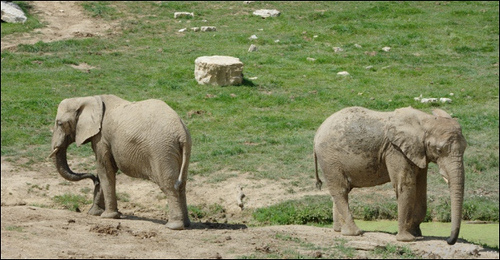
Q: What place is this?
A: It is a field.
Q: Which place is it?
A: It is a field.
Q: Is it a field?
A: Yes, it is a field.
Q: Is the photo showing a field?
A: Yes, it is showing a field.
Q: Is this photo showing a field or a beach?
A: It is showing a field.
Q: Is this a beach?
A: No, it is a field.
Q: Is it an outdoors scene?
A: Yes, it is outdoors.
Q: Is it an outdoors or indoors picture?
A: It is outdoors.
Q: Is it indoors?
A: No, it is outdoors.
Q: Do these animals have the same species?
A: Yes, all the animals are elephants.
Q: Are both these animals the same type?
A: Yes, all the animals are elephants.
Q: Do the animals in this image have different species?
A: No, all the animals are elephants.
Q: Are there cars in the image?
A: No, there are no cars.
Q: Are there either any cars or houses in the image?
A: No, there are no cars or houses.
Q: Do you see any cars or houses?
A: No, there are no cars or houses.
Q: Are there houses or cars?
A: No, there are no cars or houses.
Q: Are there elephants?
A: Yes, there is an elephant.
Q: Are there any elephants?
A: Yes, there is an elephant.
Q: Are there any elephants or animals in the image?
A: Yes, there is an elephant.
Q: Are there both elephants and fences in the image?
A: No, there is an elephant but no fences.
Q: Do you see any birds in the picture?
A: No, there are no birds.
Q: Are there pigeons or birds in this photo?
A: No, there are no birds or pigeons.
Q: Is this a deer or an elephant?
A: This is an elephant.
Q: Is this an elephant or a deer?
A: This is an elephant.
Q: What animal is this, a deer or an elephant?
A: This is an elephant.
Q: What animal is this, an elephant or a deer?
A: This is an elephant.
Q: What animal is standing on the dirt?
A: The elephant is standing on the dirt.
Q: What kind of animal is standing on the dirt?
A: The animal is an elephant.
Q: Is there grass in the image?
A: Yes, there is grass.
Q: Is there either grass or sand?
A: Yes, there is grass.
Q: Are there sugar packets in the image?
A: No, there are no sugar packets.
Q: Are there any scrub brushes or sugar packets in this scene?
A: No, there are no sugar packets or scrub brushes.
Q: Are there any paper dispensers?
A: No, there are no paper dispensers.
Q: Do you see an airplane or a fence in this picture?
A: No, there are no fences or airplanes.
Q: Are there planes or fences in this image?
A: No, there are no fences or planes.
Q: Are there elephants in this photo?
A: Yes, there is an elephant.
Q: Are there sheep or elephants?
A: Yes, there is an elephant.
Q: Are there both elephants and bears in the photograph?
A: No, there is an elephant but no bears.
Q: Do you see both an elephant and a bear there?
A: No, there is an elephant but no bears.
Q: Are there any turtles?
A: No, there are no turtles.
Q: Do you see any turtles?
A: No, there are no turtles.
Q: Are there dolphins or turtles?
A: No, there are no turtles or dolphins.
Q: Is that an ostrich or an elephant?
A: That is an elephant.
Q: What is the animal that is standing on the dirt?
A: The animal is an elephant.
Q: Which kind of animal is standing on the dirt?
A: The animal is an elephant.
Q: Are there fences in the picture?
A: No, there are no fences.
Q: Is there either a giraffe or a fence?
A: No, there are no fences or giraffes.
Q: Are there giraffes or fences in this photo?
A: No, there are no fences or giraffes.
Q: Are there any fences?
A: No, there are no fences.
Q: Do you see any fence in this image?
A: No, there are no fences.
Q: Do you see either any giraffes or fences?
A: No, there are no fences or giraffes.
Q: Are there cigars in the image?
A: No, there are no cigars.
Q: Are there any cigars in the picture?
A: No, there are no cigars.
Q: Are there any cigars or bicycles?
A: No, there are no cigars or bicycles.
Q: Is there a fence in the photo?
A: No, there are no fences.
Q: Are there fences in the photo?
A: No, there are no fences.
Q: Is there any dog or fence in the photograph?
A: No, there are no fences or dogs.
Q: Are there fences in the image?
A: No, there are no fences.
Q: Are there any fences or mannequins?
A: No, there are no fences or mannequins.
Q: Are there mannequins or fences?
A: No, there are no fences or mannequins.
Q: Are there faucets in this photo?
A: No, there are no faucets.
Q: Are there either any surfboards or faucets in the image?
A: No, there are no faucets or surfboards.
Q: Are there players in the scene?
A: No, there are no players.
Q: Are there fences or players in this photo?
A: No, there are no players or fences.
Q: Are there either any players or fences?
A: No, there are no players or fences.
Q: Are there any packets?
A: No, there are no packets.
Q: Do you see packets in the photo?
A: No, there are no packets.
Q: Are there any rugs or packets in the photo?
A: No, there are no packets or rugs.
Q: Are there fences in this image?
A: No, there are no fences.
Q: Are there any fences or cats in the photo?
A: No, there are no fences or cats.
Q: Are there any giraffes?
A: No, there are no giraffes.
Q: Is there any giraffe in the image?
A: No, there are no giraffes.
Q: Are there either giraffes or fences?
A: No, there are no giraffes or fences.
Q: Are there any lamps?
A: No, there are no lamps.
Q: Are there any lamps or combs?
A: No, there are no lamps or combs.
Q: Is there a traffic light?
A: No, there are no traffic lights.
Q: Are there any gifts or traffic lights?
A: No, there are no traffic lights or gifts.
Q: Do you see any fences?
A: No, there are no fences.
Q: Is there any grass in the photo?
A: Yes, there is grass.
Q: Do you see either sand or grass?
A: Yes, there is grass.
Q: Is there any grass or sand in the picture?
A: Yes, there is grass.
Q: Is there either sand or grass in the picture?
A: Yes, there is grass.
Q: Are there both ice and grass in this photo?
A: No, there is grass but no ice.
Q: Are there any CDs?
A: No, there are no cds.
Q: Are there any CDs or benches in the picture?
A: No, there are no CDs or benches.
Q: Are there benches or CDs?
A: No, there are no CDs or benches.